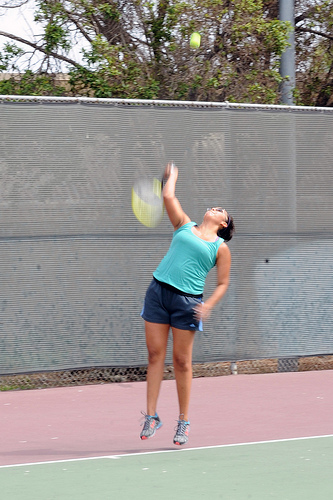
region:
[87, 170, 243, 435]
woman holding tennis racket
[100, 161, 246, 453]
woman swinging tennis racket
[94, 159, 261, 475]
woman jumping in air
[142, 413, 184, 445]
grey and pink tennis shoes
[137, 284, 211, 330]
blue and white tennis shorts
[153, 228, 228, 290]
blue tennis top on girl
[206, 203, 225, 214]
white glasses on face of woman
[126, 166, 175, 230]
yellow and black tennis racket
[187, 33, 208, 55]
yellow tennis ball in air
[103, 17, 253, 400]
girl about to serve tennis ball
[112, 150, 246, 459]
A woman is playing tennis.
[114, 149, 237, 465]
The woman is jumping.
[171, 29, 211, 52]
A tennis ball is in the air.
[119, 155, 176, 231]
The racket is yellow.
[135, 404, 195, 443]
The woman is wearing sneakers.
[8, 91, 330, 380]
There is a fence behind the court.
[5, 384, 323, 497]
The woman is on a tennis court.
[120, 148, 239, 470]
The woman is looking up at the ball.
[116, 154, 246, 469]
The woman is trying to hit the ball.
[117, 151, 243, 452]
A woman is in shorts and a tee shirt.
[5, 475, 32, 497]
Part of green painted concrete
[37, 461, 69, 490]
Part of green painted concrete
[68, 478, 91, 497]
Part of green painted concrete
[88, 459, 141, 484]
Part of green painted concrete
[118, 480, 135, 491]
Part of green painted concrete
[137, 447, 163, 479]
Part of green painted concrete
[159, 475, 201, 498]
Part of green painted concrete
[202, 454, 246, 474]
Part of green painted concrete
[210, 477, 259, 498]
Part of green painted concrete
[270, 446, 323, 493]
Part of green painted concrete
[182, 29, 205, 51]
Tennis ball flying through the air.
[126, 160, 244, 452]
The lady has jumped into the air.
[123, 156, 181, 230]
Yellow tennis racket swinging full speed.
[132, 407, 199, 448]
Gray tennis shoes with orange, blue and black highlights.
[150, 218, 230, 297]
Light blue tank top to keep cool.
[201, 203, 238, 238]
Lady wearing glasses to see ball.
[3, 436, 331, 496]
Green tennis court with white stripe.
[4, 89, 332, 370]
Gray netting on fence to make ball bounce back.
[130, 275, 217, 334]
Navy blue shorts with light blue trim.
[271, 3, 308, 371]
Gray metal pole behind the fence.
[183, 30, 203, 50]
a yellow ball in the air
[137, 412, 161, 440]
woman wearing pink and blue shoe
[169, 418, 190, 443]
woman wearing a pink and blue shoe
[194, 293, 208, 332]
blue stripe on woman's shorts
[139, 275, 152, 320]
blue stripe on woman's shorts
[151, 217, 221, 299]
woman wearing a green shirt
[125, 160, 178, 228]
woman holding a tennis racket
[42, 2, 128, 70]
branch on a tree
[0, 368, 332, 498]
tennis court is red and green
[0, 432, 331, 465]
white stripe on the tennis court